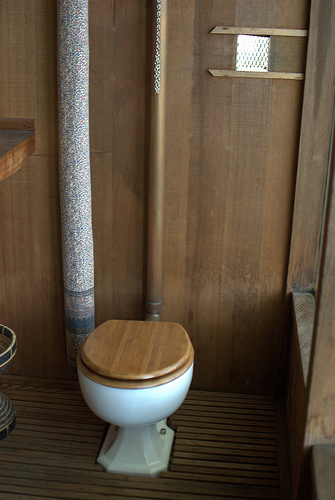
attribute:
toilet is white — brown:
[60, 371, 209, 499]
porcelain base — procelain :
[74, 380, 195, 480]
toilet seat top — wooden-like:
[66, 305, 205, 398]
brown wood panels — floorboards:
[189, 408, 278, 498]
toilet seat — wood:
[62, 313, 220, 401]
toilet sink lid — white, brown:
[61, 318, 201, 410]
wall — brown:
[125, 83, 257, 276]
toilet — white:
[66, 367, 183, 465]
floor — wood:
[209, 435, 256, 489]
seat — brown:
[70, 336, 200, 391]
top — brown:
[78, 310, 196, 383]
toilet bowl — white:
[70, 312, 207, 480]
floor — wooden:
[3, 370, 314, 486]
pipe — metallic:
[137, 1, 174, 318]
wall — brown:
[4, 4, 304, 404]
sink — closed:
[69, 307, 179, 483]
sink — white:
[81, 319, 200, 479]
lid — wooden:
[82, 312, 197, 386]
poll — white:
[53, 4, 96, 342]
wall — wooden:
[195, 108, 257, 342]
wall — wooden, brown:
[210, 104, 289, 348]